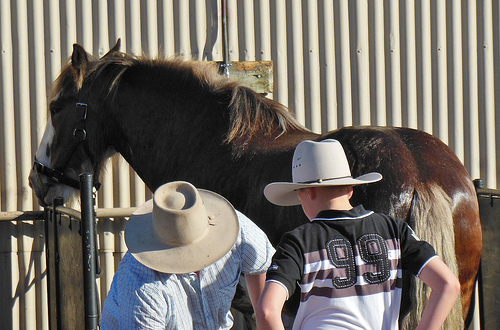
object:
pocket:
[218, 262, 241, 306]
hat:
[263, 139, 383, 207]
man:
[99, 181, 276, 329]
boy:
[255, 139, 460, 328]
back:
[303, 217, 400, 330]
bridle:
[32, 80, 103, 193]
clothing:
[267, 204, 438, 329]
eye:
[51, 108, 61, 115]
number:
[358, 234, 390, 284]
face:
[28, 97, 106, 204]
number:
[327, 239, 357, 288]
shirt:
[99, 208, 275, 329]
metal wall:
[0, 0, 499, 209]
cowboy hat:
[124, 180, 241, 273]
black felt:
[298, 176, 352, 184]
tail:
[412, 182, 468, 330]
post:
[80, 172, 98, 329]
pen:
[0, 178, 499, 329]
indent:
[153, 181, 196, 212]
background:
[0, 0, 495, 329]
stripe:
[416, 256, 437, 277]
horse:
[28, 38, 481, 330]